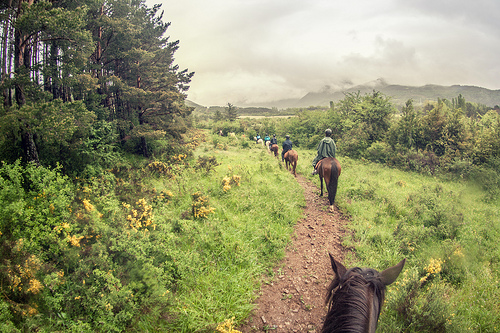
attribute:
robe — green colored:
[311, 135, 338, 165]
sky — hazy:
[145, 1, 497, 108]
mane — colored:
[336, 277, 360, 332]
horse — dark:
[311, 247, 407, 332]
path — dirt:
[256, 124, 346, 309]